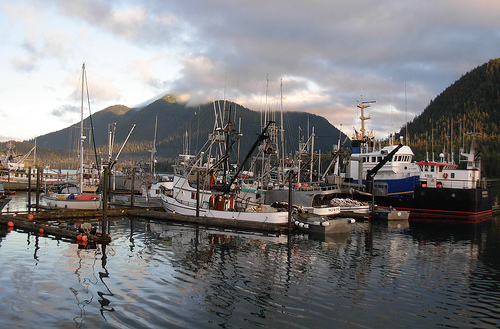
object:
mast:
[76, 62, 90, 194]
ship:
[156, 93, 299, 224]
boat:
[38, 62, 103, 210]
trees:
[397, 52, 498, 156]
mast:
[347, 93, 395, 164]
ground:
[391, 190, 417, 232]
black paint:
[419, 187, 491, 213]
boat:
[109, 179, 163, 208]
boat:
[159, 174, 291, 231]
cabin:
[172, 171, 212, 215]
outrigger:
[227, 119, 274, 187]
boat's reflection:
[147, 216, 295, 277]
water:
[30, 253, 456, 304]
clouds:
[189, 21, 396, 91]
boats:
[154, 111, 329, 228]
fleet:
[0, 62, 499, 223]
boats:
[149, 90, 492, 225]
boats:
[0, 63, 173, 211]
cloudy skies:
[0, 0, 500, 143]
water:
[0, 186, 499, 327]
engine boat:
[288, 200, 358, 236]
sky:
[17, 10, 154, 51]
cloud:
[170, 50, 268, 87]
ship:
[318, 109, 494, 236]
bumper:
[4, 206, 111, 261]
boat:
[333, 137, 420, 199]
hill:
[0, 57, 499, 169]